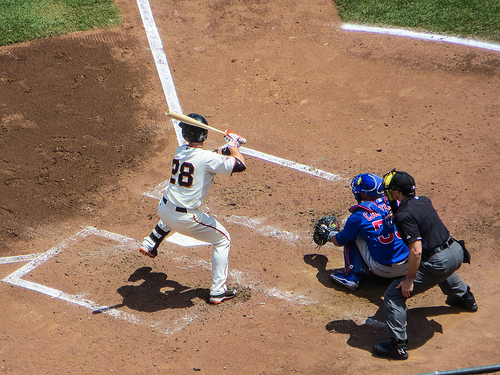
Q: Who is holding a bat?
A: A baseball player.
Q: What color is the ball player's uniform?
A: White.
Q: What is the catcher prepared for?
A: The catcher is ready to catch the ball.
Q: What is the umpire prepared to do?
A: The umpire is ready to call the ball.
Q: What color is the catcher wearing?
A: The catcher is wearing blue.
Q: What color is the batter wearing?
A: White.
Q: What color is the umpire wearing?
A: Black and grey.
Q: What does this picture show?
A: Players at a baseball game.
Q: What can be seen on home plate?
A: The batter's shadow on the ground.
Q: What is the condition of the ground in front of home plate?
A: The ground in front of home plate appears wet.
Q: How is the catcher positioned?
A: Crouching.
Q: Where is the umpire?
A: Behind the catcher.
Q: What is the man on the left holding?
A: A baseball bat.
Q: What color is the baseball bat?
A: Tan.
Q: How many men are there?
A: Three.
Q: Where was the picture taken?
A: A baseball diamond.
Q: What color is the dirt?
A: Brown.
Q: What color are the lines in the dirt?
A: White.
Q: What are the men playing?
A: Baseball.